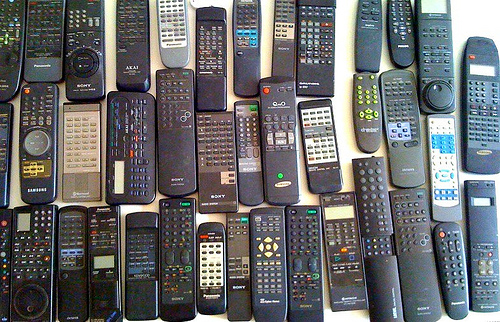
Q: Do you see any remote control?
A: Yes, there is a remote control.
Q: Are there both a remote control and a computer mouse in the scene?
A: No, there is a remote control but no computer mice.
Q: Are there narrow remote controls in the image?
A: Yes, there is a narrow remote control.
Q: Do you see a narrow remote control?
A: Yes, there is a narrow remote control.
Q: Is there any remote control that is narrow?
A: Yes, there is a remote control that is narrow.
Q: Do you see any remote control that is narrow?
A: Yes, there is a remote control that is narrow.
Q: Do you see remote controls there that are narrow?
A: Yes, there is a remote control that is narrow.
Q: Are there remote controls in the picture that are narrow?
A: Yes, there is a remote control that is narrow.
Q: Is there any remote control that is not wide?
A: Yes, there is a narrow remote control.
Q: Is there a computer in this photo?
A: No, there are no computers.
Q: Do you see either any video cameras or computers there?
A: No, there are no computers or video cameras.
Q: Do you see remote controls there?
A: Yes, there is a remote control.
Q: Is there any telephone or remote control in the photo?
A: Yes, there is a remote control.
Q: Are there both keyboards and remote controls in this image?
A: No, there is a remote control but no keyboards.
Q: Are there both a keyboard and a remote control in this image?
A: No, there is a remote control but no keyboards.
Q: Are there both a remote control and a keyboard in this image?
A: No, there is a remote control but no keyboards.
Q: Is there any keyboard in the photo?
A: No, there are no keyboards.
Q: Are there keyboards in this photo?
A: No, there are no keyboards.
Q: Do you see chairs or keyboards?
A: No, there are no keyboards or chairs.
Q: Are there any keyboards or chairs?
A: No, there are no keyboards or chairs.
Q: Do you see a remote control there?
A: Yes, there is a remote control.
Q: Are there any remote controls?
A: Yes, there is a remote control.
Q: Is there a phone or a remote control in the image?
A: Yes, there is a remote control.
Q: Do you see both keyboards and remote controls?
A: No, there is a remote control but no keyboards.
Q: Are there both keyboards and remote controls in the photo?
A: No, there is a remote control but no keyboards.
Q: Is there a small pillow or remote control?
A: Yes, there is a small remote control.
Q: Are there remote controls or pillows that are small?
A: Yes, the remote control is small.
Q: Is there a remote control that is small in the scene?
A: Yes, there is a small remote control.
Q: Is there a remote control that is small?
A: Yes, there is a remote control that is small.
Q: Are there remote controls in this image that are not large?
A: Yes, there is a small remote control.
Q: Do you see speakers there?
A: No, there are no speakers.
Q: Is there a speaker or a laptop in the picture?
A: No, there are no speakers or laptops.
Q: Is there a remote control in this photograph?
A: Yes, there is a remote control.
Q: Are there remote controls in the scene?
A: Yes, there is a remote control.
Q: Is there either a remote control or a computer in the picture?
A: Yes, there is a remote control.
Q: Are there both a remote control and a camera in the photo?
A: No, there is a remote control but no cameras.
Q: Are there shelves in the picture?
A: No, there are no shelves.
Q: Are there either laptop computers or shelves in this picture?
A: No, there are no shelves or laptop computers.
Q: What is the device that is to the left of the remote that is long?
A: The device is a screen.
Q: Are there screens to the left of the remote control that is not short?
A: Yes, there is a screen to the left of the remote.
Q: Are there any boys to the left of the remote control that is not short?
A: No, there is a screen to the left of the remote.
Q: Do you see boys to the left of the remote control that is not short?
A: No, there is a screen to the left of the remote.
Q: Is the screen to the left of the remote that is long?
A: Yes, the screen is to the left of the remote control.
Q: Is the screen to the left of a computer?
A: No, the screen is to the left of the remote control.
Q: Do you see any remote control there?
A: Yes, there is a remote control.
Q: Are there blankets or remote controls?
A: Yes, there is a remote control.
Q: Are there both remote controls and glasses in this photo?
A: No, there is a remote control but no glasses.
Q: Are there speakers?
A: No, there are no speakers.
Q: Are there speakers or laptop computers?
A: No, there are no speakers or laptop computers.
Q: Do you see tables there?
A: Yes, there is a table.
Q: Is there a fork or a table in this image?
A: Yes, there is a table.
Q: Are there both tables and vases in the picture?
A: No, there is a table but no vases.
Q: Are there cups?
A: No, there are no cups.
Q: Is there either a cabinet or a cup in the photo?
A: No, there are no cups or cabinets.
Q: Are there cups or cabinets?
A: No, there are no cups or cabinets.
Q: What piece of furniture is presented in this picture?
A: The piece of furniture is a table.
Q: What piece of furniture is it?
A: The piece of furniture is a table.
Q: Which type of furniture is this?
A: That is a table.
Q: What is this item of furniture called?
A: That is a table.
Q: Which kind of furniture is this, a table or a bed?
A: That is a table.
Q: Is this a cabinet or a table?
A: This is a table.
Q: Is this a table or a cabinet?
A: This is a table.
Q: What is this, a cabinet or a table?
A: This is a table.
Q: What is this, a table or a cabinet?
A: This is a table.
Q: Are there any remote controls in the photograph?
A: Yes, there is a remote control.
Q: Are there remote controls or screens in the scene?
A: Yes, there is a remote control.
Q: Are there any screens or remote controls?
A: Yes, there is a remote control.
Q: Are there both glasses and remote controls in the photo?
A: No, there is a remote control but no glasses.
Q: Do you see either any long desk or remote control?
A: Yes, there is a long remote control.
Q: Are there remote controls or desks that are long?
A: Yes, the remote control is long.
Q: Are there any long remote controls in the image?
A: Yes, there is a long remote control.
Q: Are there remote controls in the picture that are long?
A: Yes, there is a remote control that is long.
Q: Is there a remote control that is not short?
A: Yes, there is a long remote control.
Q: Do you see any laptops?
A: No, there are no laptops.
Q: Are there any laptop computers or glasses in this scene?
A: No, there are no laptop computers or glasses.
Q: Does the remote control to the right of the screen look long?
A: Yes, the remote is long.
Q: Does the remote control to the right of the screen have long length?
A: Yes, the remote is long.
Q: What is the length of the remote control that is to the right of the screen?
A: The remote is long.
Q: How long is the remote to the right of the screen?
A: The remote control is long.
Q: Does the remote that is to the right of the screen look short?
A: No, the remote control is long.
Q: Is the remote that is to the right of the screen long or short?
A: The remote is long.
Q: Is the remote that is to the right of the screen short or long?
A: The remote is long.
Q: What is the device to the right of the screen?
A: The device is a remote control.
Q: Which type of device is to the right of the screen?
A: The device is a remote control.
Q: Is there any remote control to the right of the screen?
A: Yes, there is a remote control to the right of the screen.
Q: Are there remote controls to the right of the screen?
A: Yes, there is a remote control to the right of the screen.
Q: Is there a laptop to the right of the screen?
A: No, there is a remote control to the right of the screen.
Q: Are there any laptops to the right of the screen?
A: No, there is a remote control to the right of the screen.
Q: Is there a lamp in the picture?
A: No, there are no lamps.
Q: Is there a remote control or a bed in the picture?
A: Yes, there is a remote control.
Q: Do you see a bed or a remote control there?
A: Yes, there is a remote control.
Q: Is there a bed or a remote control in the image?
A: Yes, there is a remote control.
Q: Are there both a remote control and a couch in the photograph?
A: No, there is a remote control but no couches.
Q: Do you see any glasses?
A: No, there are no glasses.